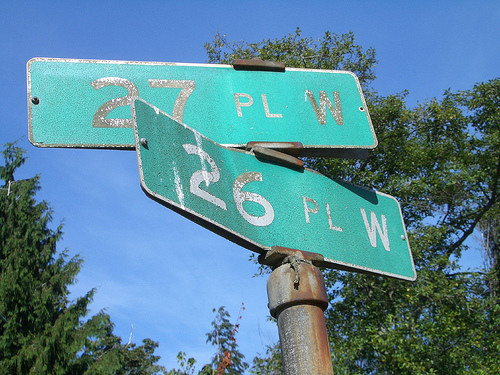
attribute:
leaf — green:
[377, 318, 417, 353]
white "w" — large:
[360, 206, 392, 251]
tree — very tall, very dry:
[1, 134, 112, 374]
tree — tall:
[0, 138, 167, 373]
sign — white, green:
[138, 105, 416, 287]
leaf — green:
[55, 230, 64, 242]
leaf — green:
[449, 247, 461, 259]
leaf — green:
[39, 207, 46, 215]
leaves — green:
[12, 191, 69, 308]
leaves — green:
[376, 93, 498, 209]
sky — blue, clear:
[368, 35, 475, 81]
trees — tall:
[201, 28, 491, 371]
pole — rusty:
[256, 246, 328, 372]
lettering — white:
[59, 54, 406, 268]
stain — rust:
[299, 266, 335, 371]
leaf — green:
[86, 347, 96, 360]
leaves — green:
[431, 270, 465, 325]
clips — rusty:
[260, 131, 325, 181]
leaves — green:
[21, 267, 35, 281]